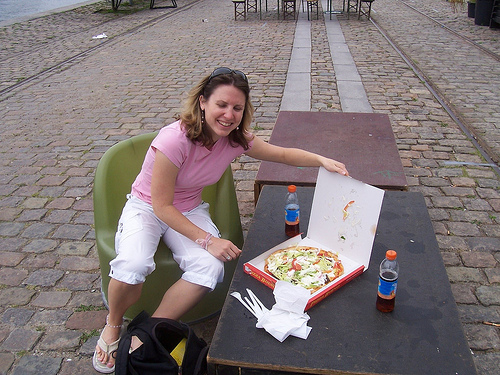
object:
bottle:
[375, 249, 403, 314]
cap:
[384, 249, 398, 261]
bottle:
[284, 184, 301, 238]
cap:
[287, 185, 298, 193]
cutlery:
[228, 283, 272, 326]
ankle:
[105, 312, 124, 336]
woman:
[87, 55, 352, 373]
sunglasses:
[209, 65, 246, 81]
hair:
[177, 64, 256, 152]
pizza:
[262, 246, 346, 296]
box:
[241, 160, 389, 314]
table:
[353, 320, 448, 367]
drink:
[376, 273, 398, 312]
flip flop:
[87, 319, 126, 373]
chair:
[93, 124, 243, 328]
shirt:
[131, 117, 254, 212]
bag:
[121, 309, 211, 368]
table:
[285, 110, 383, 135]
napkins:
[252, 277, 317, 344]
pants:
[103, 198, 226, 292]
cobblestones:
[38, 124, 85, 154]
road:
[2, 23, 100, 348]